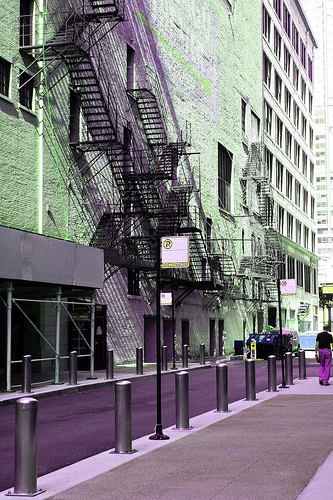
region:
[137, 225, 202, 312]
a sign on a pole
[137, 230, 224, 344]
a sign on a metal pole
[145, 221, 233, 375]
a pole with a sign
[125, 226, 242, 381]
a metal pole with a sign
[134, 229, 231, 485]
a pole on the side walk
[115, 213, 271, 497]
a metal pole on sidewalk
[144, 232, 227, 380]
a sign on the sidewalk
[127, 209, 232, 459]
a sidewalk with sign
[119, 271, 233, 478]
a sidewalk wiht sign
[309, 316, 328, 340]
a man walking on the sidewalk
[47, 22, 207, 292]
black ladders on building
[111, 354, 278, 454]
grey poles near road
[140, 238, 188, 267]
red and white sign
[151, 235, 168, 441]
sign on black post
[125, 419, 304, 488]
grey sidewalk near road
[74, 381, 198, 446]
road is dark grey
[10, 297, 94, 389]
grey posts under awning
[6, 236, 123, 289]
grey awning over storefront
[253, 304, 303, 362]
van parked in distance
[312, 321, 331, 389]
man walking on sidewalk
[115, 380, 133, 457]
a pole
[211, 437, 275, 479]
the sidewalk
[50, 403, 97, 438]
the street is black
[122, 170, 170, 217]
the stairs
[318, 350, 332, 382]
person is wearing pants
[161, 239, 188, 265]
a sign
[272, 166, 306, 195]
windows on the building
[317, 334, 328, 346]
a black shirt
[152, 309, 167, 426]
the pole is black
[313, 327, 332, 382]
a person is walking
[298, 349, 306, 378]
large silver metal pole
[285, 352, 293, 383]
large silver metal pole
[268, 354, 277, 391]
large silver metal pole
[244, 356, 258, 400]
large silver metal pole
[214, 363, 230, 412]
large silver metal pole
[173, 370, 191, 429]
large silver metal pole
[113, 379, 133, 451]
large silver metal pole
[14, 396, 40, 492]
large silver metal pole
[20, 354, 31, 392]
large silver metal pole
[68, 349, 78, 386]
large silver metal pole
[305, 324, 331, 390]
man in purple pants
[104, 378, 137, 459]
silver metal pole beside road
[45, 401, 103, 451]
black pavement on road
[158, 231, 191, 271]
parking side hanging on black pole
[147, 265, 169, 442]
black metal street sign pole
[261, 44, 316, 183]
row of windows on side of building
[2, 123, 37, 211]
green paint on side of building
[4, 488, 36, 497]
silver bolts on metal pole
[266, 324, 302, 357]
vehicle parked beside road